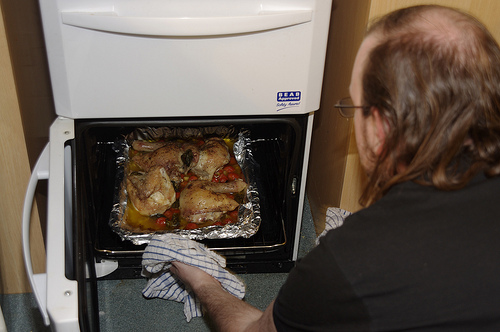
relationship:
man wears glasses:
[165, 3, 498, 332] [335, 97, 366, 118]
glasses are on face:
[335, 97, 366, 118] [345, 66, 371, 168]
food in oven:
[121, 129, 243, 223] [59, 108, 300, 265]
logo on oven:
[276, 87, 303, 109] [19, 2, 336, 322]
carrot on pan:
[155, 217, 167, 225] [107, 120, 262, 244]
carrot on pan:
[155, 217, 167, 225] [89, 46, 352, 320]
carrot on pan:
[228, 172, 239, 180] [113, 217, 262, 242]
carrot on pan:
[224, 172, 239, 179] [107, 120, 262, 244]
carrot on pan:
[230, 210, 237, 217] [107, 120, 262, 244]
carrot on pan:
[163, 208, 173, 218] [107, 120, 262, 244]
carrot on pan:
[228, 172, 239, 180] [107, 120, 262, 244]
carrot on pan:
[153, 215, 168, 229] [107, 120, 262, 244]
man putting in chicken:
[172, 3, 499, 329] [130, 136, 247, 217]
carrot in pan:
[184, 221, 196, 228] [111, 224, 260, 243]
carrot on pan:
[182, 167, 199, 181] [113, 133, 260, 240]